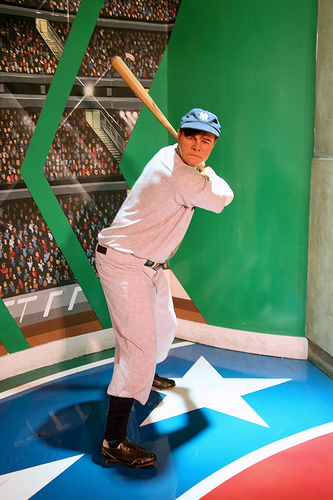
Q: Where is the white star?
A: Floor.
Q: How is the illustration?
A: Colorful.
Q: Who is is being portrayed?
A: Babe Ruth.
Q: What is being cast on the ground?
A: A shadow.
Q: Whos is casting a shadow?
A: The baseball player.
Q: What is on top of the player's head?
A: A baseball cap.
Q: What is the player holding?
A: A bat.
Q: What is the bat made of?
A: Wood.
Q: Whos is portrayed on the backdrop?
A: Spectators.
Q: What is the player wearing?
A: A baseball uniform.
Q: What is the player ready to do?
A: Hit the ball.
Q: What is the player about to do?
A: Swing the bat.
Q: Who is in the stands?
A: Fans.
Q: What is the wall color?
A: Green.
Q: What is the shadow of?
A: Player.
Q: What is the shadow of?
A: Player.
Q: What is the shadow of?
A: Player.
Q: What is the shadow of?
A: Player.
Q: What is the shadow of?
A: Player.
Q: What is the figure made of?
A: Wax.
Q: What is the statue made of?
A: Wax.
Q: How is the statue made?
A: Wax.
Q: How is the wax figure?
A: Life like.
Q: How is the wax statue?
A: Life size.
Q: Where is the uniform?
A: The man.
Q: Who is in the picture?
A: A baseball player.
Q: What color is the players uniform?
A: White.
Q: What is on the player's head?
A: A hat.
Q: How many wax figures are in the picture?
A: One.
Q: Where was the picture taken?
A: A wax museum.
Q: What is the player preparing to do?
A: Hit the ball.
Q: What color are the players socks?
A: Black.